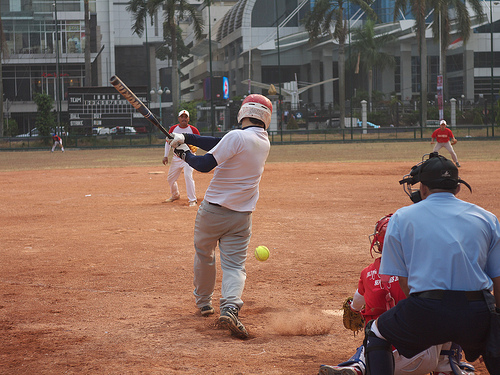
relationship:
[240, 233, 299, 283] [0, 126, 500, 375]
baseball on floor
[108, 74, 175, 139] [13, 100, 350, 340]
bat in park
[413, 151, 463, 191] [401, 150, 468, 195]
hat on head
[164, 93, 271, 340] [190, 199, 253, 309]
baseball player wearing pants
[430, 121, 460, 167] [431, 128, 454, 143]
person wearing baseball jersey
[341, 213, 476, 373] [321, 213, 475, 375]
catcher wearing catcher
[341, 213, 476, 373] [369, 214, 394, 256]
catcher wearing mask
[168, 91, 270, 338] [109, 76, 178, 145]
baseball player swinging bat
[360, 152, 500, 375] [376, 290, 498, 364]
catcher wearing shorts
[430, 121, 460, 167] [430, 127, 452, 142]
person wearing shirt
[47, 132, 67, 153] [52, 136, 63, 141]
person wearing red shirt